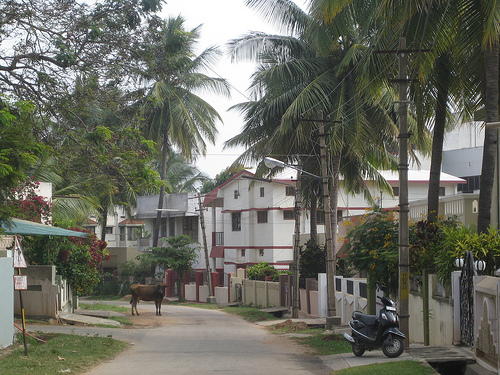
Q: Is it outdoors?
A: Yes, it is outdoors.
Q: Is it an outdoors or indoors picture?
A: It is outdoors.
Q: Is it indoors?
A: No, it is outdoors.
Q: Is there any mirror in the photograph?
A: No, there are no mirrors.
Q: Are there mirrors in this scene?
A: No, there are no mirrors.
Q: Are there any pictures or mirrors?
A: No, there are no mirrors or pictures.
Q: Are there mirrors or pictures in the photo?
A: No, there are no mirrors or pictures.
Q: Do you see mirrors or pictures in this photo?
A: No, there are no mirrors or pictures.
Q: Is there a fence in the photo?
A: Yes, there is a fence.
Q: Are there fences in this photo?
A: Yes, there is a fence.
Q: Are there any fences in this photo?
A: Yes, there is a fence.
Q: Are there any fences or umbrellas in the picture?
A: Yes, there is a fence.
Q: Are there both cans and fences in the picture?
A: No, there is a fence but no cans.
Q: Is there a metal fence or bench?
A: Yes, there is a metal fence.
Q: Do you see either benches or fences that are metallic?
A: Yes, the fence is metallic.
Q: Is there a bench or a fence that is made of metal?
A: Yes, the fence is made of metal.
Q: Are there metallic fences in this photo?
A: Yes, there is a metal fence.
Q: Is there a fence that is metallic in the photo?
A: Yes, there is a metal fence.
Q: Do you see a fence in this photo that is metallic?
A: Yes, there is a fence that is metallic.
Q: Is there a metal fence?
A: Yes, there is a fence that is made of metal.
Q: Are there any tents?
A: No, there are no tents.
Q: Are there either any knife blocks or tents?
A: No, there are no tents or knife blocks.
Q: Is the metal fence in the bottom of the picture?
A: Yes, the fence is in the bottom of the image.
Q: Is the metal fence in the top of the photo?
A: No, the fence is in the bottom of the image.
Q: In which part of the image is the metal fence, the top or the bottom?
A: The fence is in the bottom of the image.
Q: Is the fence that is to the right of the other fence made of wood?
A: No, the fence is made of metal.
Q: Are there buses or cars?
A: No, there are no cars or buses.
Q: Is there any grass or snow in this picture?
A: Yes, there is grass.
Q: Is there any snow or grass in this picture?
A: Yes, there is grass.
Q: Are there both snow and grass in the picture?
A: No, there is grass but no snow.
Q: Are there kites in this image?
A: No, there are no kites.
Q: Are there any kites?
A: No, there are no kites.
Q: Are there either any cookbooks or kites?
A: No, there are no kites or cookbooks.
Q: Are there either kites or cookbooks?
A: No, there are no kites or cookbooks.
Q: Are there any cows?
A: Yes, there is a cow.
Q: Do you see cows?
A: Yes, there is a cow.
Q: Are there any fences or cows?
A: Yes, there is a cow.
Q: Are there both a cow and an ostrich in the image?
A: No, there is a cow but no ostriches.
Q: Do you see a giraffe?
A: No, there are no giraffes.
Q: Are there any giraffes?
A: No, there are no giraffes.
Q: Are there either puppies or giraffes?
A: No, there are no giraffes or puppies.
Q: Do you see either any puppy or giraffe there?
A: No, there are no giraffes or puppies.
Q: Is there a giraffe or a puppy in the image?
A: No, there are no giraffes or puppies.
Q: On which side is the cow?
A: The cow is on the left of the image.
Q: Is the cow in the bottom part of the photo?
A: Yes, the cow is in the bottom of the image.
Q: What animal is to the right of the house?
A: The animal is a cow.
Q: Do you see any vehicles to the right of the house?
A: No, there is a cow to the right of the house.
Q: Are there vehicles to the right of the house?
A: No, there is a cow to the right of the house.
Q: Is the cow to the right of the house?
A: Yes, the cow is to the right of the house.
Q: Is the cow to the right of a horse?
A: No, the cow is to the right of the house.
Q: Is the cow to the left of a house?
A: No, the cow is to the right of a house.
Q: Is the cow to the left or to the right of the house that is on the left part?
A: The cow is to the right of the house.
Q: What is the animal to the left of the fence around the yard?
A: The animal is a cow.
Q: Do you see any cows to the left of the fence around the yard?
A: Yes, there is a cow to the left of the fence.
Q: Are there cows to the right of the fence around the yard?
A: No, the cow is to the left of the fence.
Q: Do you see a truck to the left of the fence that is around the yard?
A: No, there is a cow to the left of the fence.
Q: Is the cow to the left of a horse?
A: No, the cow is to the left of a fence.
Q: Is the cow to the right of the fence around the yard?
A: No, the cow is to the left of the fence.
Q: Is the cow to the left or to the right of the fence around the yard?
A: The cow is to the left of the fence.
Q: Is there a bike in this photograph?
A: Yes, there is a bike.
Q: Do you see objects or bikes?
A: Yes, there is a bike.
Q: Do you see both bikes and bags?
A: No, there is a bike but no bags.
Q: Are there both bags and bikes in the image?
A: No, there is a bike but no bags.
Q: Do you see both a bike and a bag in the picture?
A: No, there is a bike but no bags.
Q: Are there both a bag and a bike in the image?
A: No, there is a bike but no bags.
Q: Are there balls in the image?
A: No, there are no balls.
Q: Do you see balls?
A: No, there are no balls.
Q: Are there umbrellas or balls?
A: No, there are no balls or umbrellas.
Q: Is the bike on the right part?
A: Yes, the bike is on the right of the image.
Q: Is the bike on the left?
A: No, the bike is on the right of the image.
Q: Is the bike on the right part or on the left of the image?
A: The bike is on the right of the image.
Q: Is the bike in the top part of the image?
A: No, the bike is in the bottom of the image.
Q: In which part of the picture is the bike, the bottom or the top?
A: The bike is in the bottom of the image.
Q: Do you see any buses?
A: No, there are no buses.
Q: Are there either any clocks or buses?
A: No, there are no buses or clocks.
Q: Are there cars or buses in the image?
A: No, there are no buses or cars.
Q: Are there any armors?
A: No, there are no armors.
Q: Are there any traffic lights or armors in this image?
A: No, there are no armors or traffic lights.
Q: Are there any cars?
A: No, there are no cars.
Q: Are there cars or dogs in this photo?
A: No, there are no cars or dogs.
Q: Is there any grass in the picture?
A: Yes, there is grass.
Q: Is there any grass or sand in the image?
A: Yes, there is grass.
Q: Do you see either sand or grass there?
A: Yes, there is grass.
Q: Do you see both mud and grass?
A: No, there is grass but no mud.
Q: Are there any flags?
A: No, there are no flags.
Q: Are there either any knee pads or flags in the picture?
A: No, there are no flags or knee pads.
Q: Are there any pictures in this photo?
A: No, there are no pictures.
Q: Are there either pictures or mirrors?
A: No, there are no pictures or mirrors.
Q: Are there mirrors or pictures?
A: No, there are no pictures or mirrors.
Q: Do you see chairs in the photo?
A: No, there are no chairs.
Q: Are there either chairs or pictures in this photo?
A: No, there are no chairs or pictures.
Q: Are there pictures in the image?
A: No, there are no pictures.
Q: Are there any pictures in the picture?
A: No, there are no pictures.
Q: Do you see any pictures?
A: No, there are no pictures.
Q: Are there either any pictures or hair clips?
A: No, there are no pictures or hair clips.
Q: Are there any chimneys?
A: No, there are no chimneys.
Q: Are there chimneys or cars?
A: No, there are no chimneys or cars.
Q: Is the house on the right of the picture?
A: No, the house is on the left of the image.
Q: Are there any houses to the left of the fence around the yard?
A: Yes, there is a house to the left of the fence.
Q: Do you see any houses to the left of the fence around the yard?
A: Yes, there is a house to the left of the fence.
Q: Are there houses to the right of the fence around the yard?
A: No, the house is to the left of the fence.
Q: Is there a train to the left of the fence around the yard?
A: No, there is a house to the left of the fence.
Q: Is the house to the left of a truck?
A: No, the house is to the left of a fence.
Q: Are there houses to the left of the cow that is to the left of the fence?
A: Yes, there is a house to the left of the cow.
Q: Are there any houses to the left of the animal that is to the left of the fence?
A: Yes, there is a house to the left of the cow.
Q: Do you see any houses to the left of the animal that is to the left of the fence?
A: Yes, there is a house to the left of the cow.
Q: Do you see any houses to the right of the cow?
A: No, the house is to the left of the cow.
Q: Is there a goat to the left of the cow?
A: No, there is a house to the left of the cow.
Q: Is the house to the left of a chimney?
A: No, the house is to the left of a cow.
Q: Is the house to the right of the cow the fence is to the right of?
A: No, the house is to the left of the cow.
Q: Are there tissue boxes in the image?
A: No, there are no tissue boxes.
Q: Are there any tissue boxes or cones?
A: No, there are no tissue boxes or cones.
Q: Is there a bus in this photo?
A: No, there are no buses.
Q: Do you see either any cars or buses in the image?
A: No, there are no buses or cars.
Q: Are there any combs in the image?
A: No, there are no combs.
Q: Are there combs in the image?
A: No, there are no combs.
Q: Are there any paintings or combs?
A: No, there are no combs or paintings.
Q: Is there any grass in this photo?
A: Yes, there is grass.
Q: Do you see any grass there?
A: Yes, there is grass.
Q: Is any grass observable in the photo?
A: Yes, there is grass.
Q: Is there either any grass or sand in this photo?
A: Yes, there is grass.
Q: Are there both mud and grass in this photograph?
A: No, there is grass but no mud.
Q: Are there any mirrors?
A: No, there are no mirrors.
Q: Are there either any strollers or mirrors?
A: No, there are no mirrors or strollers.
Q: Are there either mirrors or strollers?
A: No, there are no mirrors or strollers.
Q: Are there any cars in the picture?
A: No, there are no cars.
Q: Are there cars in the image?
A: No, there are no cars.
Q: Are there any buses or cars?
A: No, there are no cars or buses.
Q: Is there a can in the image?
A: No, there are no cans.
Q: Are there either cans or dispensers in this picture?
A: No, there are no cans or dispensers.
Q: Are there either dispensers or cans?
A: No, there are no cans or dispensers.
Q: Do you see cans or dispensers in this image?
A: No, there are no cans or dispensers.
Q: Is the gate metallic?
A: Yes, the gate is metallic.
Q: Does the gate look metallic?
A: Yes, the gate is metallic.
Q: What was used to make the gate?
A: The gate is made of metal.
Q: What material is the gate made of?
A: The gate is made of metal.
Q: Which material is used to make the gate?
A: The gate is made of metal.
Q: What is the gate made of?
A: The gate is made of metal.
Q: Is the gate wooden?
A: No, the gate is metallic.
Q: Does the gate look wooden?
A: No, the gate is metallic.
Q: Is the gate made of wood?
A: No, the gate is made of metal.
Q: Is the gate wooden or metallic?
A: The gate is metallic.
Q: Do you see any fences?
A: Yes, there is a fence.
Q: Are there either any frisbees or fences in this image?
A: Yes, there is a fence.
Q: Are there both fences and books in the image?
A: No, there is a fence but no books.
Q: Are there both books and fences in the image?
A: No, there is a fence but no books.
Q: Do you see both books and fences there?
A: No, there is a fence but no books.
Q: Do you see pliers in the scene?
A: No, there are no pliers.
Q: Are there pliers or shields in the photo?
A: No, there are no pliers or shields.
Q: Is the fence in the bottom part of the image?
A: Yes, the fence is in the bottom of the image.